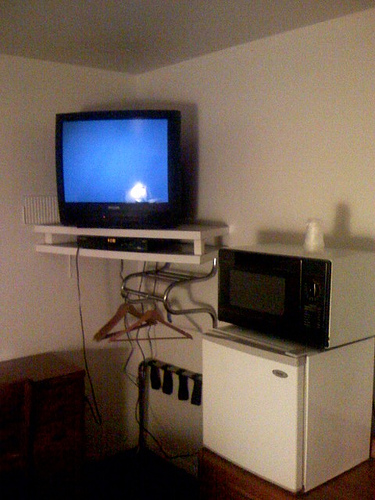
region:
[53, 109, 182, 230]
tv on the stand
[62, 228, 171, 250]
dvd player on stand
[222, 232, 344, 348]
microwave on top of refridgerator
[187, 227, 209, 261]
corner of white shelf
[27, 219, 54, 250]
corner of white shelf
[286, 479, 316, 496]
corner of white refridgerator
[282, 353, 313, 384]
corner of white refridgerator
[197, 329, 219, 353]
corner of white refridgerator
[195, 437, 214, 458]
corner of white refridgerator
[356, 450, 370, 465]
corner of white refridgerator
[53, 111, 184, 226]
Television on top of shelf is on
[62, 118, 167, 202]
Blue screen on black television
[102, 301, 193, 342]
Wooden hanger below television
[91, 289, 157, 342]
Wooden hanger below television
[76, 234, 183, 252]
Black DVD below television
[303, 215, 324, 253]
Stack of cups above microwave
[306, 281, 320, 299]
Black dial knob on microwave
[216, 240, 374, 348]
Microwave on top of white fridge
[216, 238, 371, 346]
Microwave near wooden hanger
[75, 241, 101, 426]
Black cable coming from DVD player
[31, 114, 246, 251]
a tv in a room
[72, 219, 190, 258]
a vcr in a room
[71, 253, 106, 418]
a cord to a vcr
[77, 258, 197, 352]
a hanger in a room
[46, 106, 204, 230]
a blue screen on a tv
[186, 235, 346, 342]
a microwave in a room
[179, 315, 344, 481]
a small refrigerator in a room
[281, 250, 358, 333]
a knob on a microwave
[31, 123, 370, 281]
a tv near a microwave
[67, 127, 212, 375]
a hanger under a tv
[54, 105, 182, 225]
a tv sitting in the corner of the room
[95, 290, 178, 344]
some hangers attached to a metal rail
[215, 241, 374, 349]
a microwave oven sitting on a mini fridge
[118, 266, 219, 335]
a metal rack that the hangers are attached to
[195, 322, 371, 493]
a mini fridge sitting on a shelf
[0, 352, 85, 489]
a wooden desk sitting by the wall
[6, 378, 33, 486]
a wooden chair sitting by the desk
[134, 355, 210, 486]
a sort of metal chair with some straps on it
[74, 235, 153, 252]
the vcr sitting under the tv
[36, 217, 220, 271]
the shelves the tv is sitting on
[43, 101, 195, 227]
television with blue screen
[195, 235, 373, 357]
white and black microwave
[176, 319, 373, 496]
white refrigerator on table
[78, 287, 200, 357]
two wooden hangers on bar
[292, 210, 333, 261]
several plastic cups on microwave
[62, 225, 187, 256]
dvd player on mount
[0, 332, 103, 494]
wood dresser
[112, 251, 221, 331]
chrome metal bar mounted on wall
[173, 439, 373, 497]
wooden table with refrigerator on top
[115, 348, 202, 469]
chrome bar with mat